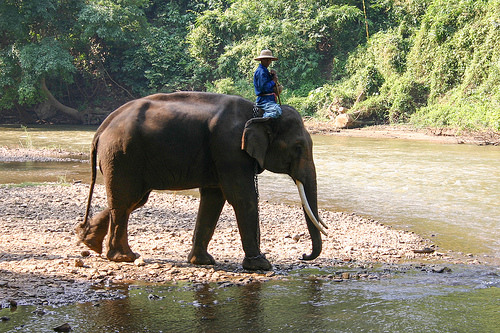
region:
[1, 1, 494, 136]
The trees in the background.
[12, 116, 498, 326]
The brown water near the trees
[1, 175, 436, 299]
The rocky road the elephant is walking on.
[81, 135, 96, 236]
The tail of the elephant.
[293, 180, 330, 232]
The tusks of the elephant.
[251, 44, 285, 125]
The man on the elephant.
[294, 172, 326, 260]
The trunk of the elephant.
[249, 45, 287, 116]
a person on the elephant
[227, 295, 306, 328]
the water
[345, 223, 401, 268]
the rocks are brown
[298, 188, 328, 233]
the tusk on the elephant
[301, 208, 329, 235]
a whte tusk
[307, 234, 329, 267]
the trunk is long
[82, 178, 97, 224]
the elephants tail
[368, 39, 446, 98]
the leaves are green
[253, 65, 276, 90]
person is wearing a blue shirt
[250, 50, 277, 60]
person is wearing a brown hat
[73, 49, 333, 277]
a man riding a elephant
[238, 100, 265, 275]
a chain on a elephants foot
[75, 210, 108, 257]
a elephants foot raised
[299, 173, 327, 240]
a white elephant tusk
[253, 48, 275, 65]
a man wearing a hat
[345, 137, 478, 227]
a body of water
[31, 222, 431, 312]
a elephant walking on a rock bank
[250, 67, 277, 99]
a man wearing a blue shirt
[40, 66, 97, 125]
a large tree on the ground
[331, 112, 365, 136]
a tree trunk on the ground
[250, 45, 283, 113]
man riding on elephant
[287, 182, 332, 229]
white tusks of the elephant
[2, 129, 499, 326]
water surrounding the elephant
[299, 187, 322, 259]
trunk of the elephant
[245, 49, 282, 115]
man wearing blue shirt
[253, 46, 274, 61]
hat man is wearing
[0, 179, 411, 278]
rocky spot elephant is standing on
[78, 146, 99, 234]
tail of the elephant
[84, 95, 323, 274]
elephant with a man riding him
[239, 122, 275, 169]
ear of the elephant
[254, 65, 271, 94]
man wearing a blue shirt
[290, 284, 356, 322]
the water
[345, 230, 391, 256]
the rocks are brown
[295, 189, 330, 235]
the tusk is white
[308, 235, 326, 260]
the elephants trunk is long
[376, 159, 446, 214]
the moving water is brown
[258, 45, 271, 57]
a person is wearing a hat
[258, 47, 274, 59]
the hat is beige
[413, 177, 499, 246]
the brown water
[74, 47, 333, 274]
Man riding an elephant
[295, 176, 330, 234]
Long tusks of the elephant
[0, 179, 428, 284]
Rock and dirt island